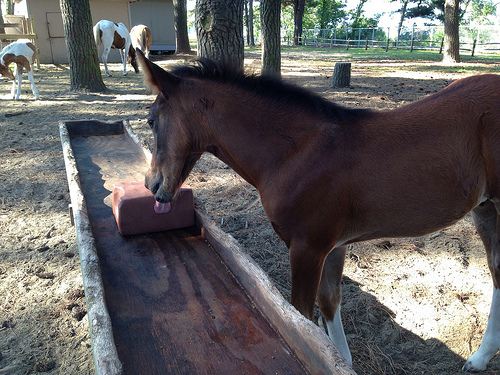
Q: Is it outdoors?
A: Yes, it is outdoors.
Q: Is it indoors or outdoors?
A: It is outdoors.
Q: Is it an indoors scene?
A: No, it is outdoors.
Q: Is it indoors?
A: No, it is outdoors.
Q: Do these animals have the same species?
A: Yes, all the animals are horses.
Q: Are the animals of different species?
A: No, all the animals are horses.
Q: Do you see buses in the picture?
A: No, there are no buses.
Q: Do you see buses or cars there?
A: No, there are no buses or cars.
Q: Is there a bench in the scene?
A: No, there are no benches.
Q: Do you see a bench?
A: No, there are no benches.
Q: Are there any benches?
A: No, there are no benches.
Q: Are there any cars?
A: No, there are no cars.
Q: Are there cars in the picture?
A: No, there are no cars.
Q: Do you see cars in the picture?
A: No, there are no cars.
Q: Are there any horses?
A: Yes, there is a horse.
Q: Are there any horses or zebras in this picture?
A: Yes, there is a horse.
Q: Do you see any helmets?
A: No, there are no helmets.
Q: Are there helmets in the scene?
A: No, there are no helmets.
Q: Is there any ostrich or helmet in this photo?
A: No, there are no helmets or ostriches.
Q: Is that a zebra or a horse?
A: That is a horse.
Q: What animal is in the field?
A: The horse is in the field.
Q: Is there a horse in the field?
A: Yes, there is a horse in the field.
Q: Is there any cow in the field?
A: No, there is a horse in the field.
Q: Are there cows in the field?
A: No, there is a horse in the field.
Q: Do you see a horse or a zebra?
A: Yes, there is a horse.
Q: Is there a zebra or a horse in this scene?
A: Yes, there is a horse.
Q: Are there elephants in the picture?
A: No, there are no elephants.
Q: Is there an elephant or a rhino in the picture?
A: No, there are no elephants or rhinos.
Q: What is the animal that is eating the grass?
A: The animal is a horse.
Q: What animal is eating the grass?
A: The animal is a horse.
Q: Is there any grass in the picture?
A: Yes, there is grass.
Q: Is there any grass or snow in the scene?
A: Yes, there is grass.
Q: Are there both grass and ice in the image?
A: No, there is grass but no ice.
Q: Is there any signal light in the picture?
A: No, there are no traffic lights.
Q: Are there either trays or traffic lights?
A: No, there are no traffic lights or trays.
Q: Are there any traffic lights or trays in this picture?
A: No, there are no traffic lights or trays.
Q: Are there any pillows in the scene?
A: No, there are no pillows.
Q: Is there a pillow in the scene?
A: No, there are no pillows.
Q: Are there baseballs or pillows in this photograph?
A: No, there are no pillows or baseballs.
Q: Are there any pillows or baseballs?
A: No, there are no pillows or baseballs.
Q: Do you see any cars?
A: No, there are no cars.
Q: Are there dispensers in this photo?
A: No, there are no dispensers.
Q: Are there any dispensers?
A: No, there are no dispensers.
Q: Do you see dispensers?
A: No, there are no dispensers.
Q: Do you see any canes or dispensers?
A: No, there are no dispensers or canes.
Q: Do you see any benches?
A: No, there are no benches.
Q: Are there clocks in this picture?
A: No, there are no clocks.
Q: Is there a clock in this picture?
A: No, there are no clocks.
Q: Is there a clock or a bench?
A: No, there are no clocks or benches.